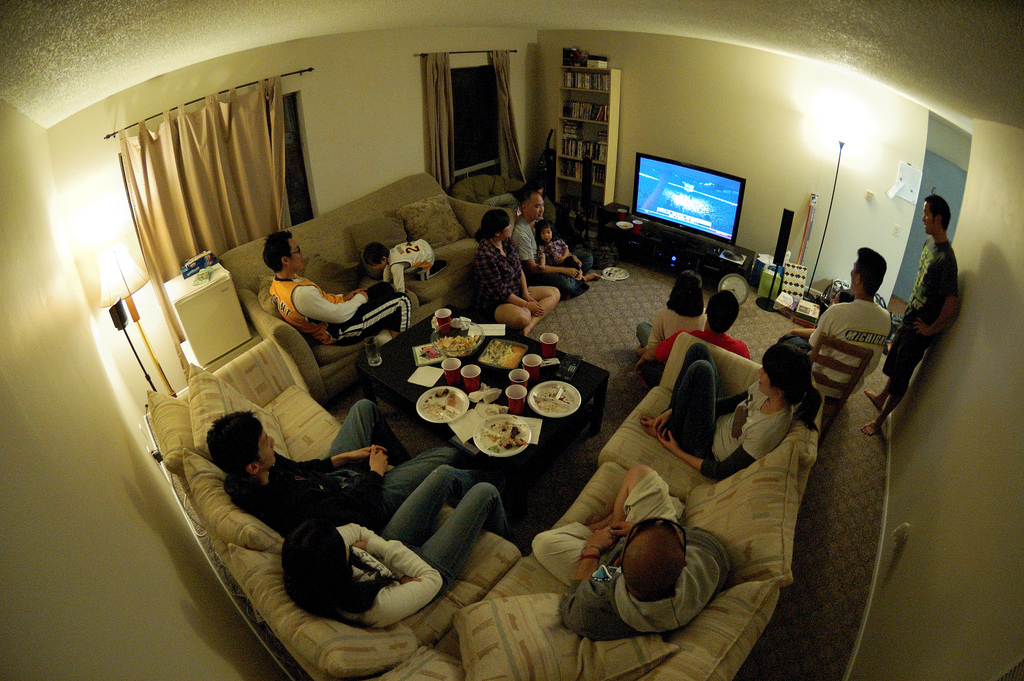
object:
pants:
[377, 464, 516, 615]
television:
[632, 151, 749, 249]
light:
[91, 243, 157, 312]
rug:
[326, 260, 888, 681]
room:
[0, 0, 1024, 681]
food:
[477, 341, 527, 370]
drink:
[506, 385, 530, 415]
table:
[354, 304, 609, 527]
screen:
[633, 157, 740, 241]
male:
[262, 228, 416, 348]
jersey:
[290, 274, 369, 323]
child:
[362, 239, 449, 293]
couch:
[217, 173, 516, 407]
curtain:
[112, 74, 287, 342]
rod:
[102, 66, 315, 142]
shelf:
[555, 66, 620, 238]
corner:
[510, 28, 560, 184]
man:
[509, 190, 604, 302]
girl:
[532, 218, 589, 283]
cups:
[506, 385, 526, 417]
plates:
[473, 413, 534, 458]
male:
[203, 399, 458, 540]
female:
[280, 465, 513, 629]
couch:
[143, 338, 520, 681]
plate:
[414, 385, 468, 424]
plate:
[528, 379, 586, 419]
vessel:
[441, 357, 463, 386]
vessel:
[460, 363, 484, 393]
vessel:
[507, 368, 529, 393]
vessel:
[521, 353, 543, 382]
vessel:
[539, 332, 559, 358]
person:
[775, 247, 893, 404]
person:
[855, 193, 964, 438]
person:
[629, 290, 753, 388]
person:
[632, 270, 711, 365]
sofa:
[597, 331, 825, 507]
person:
[638, 343, 824, 483]